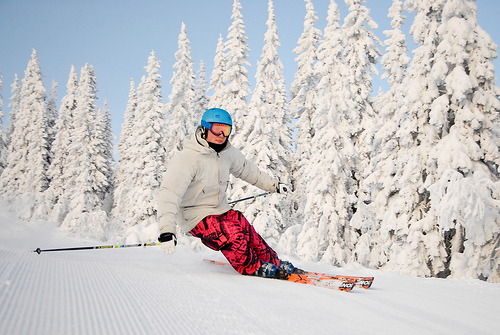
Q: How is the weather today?
A: It is clear.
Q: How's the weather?
A: It is clear.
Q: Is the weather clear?
A: Yes, it is clear.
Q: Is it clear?
A: Yes, it is clear.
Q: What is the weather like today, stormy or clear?
A: It is clear.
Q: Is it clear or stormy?
A: It is clear.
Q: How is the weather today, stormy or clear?
A: It is clear.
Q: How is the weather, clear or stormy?
A: It is clear.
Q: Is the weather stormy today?
A: No, it is clear.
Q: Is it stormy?
A: No, it is clear.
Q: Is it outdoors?
A: Yes, it is outdoors.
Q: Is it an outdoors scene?
A: Yes, it is outdoors.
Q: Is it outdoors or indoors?
A: It is outdoors.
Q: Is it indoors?
A: No, it is outdoors.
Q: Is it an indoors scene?
A: No, it is outdoors.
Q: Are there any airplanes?
A: No, there are no airplanes.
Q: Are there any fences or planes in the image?
A: No, there are no planes or fences.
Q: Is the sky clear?
A: Yes, the sky is clear.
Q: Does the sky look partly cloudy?
A: No, the sky is clear.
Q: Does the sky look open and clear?
A: Yes, the sky is open and clear.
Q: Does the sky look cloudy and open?
A: No, the sky is open but clear.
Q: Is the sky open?
A: Yes, the sky is open.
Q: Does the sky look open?
A: Yes, the sky is open.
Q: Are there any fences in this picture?
A: No, there are no fences.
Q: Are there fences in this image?
A: No, there are no fences.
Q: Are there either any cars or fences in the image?
A: No, there are no fences or cars.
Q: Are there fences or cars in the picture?
A: No, there are no fences or cars.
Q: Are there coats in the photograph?
A: Yes, there is a coat.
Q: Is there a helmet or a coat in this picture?
A: Yes, there is a coat.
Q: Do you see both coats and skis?
A: Yes, there are both a coat and skis.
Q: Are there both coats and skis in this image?
A: Yes, there are both a coat and skis.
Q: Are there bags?
A: No, there are no bags.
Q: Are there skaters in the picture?
A: No, there are no skaters.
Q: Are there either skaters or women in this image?
A: No, there are no skaters or women.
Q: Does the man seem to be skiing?
A: Yes, the man is skiing.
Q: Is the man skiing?
A: Yes, the man is skiing.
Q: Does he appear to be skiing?
A: Yes, the man is skiing.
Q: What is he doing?
A: The man is skiing.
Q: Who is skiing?
A: The man is skiing.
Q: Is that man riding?
A: No, the man is skiing.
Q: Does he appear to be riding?
A: No, the man is skiing.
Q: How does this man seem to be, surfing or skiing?
A: The man is skiing.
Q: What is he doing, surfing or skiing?
A: The man is skiing.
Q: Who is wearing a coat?
A: The man is wearing a coat.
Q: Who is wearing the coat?
A: The man is wearing a coat.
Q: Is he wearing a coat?
A: Yes, the man is wearing a coat.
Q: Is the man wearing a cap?
A: No, the man is wearing a coat.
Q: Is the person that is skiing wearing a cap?
A: No, the man is wearing a coat.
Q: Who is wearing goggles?
A: The man is wearing goggles.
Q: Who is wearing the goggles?
A: The man is wearing goggles.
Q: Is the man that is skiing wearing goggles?
A: Yes, the man is wearing goggles.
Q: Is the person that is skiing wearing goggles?
A: Yes, the man is wearing goggles.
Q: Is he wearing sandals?
A: No, the man is wearing goggles.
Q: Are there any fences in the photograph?
A: No, there are no fences.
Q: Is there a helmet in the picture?
A: Yes, there is a helmet.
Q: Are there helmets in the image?
A: Yes, there is a helmet.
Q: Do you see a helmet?
A: Yes, there is a helmet.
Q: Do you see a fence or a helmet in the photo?
A: Yes, there is a helmet.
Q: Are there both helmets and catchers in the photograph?
A: No, there is a helmet but no catchers.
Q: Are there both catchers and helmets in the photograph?
A: No, there is a helmet but no catchers.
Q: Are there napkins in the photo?
A: No, there are no napkins.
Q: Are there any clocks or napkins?
A: No, there are no napkins or clocks.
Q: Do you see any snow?
A: Yes, there is snow.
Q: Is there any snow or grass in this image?
A: Yes, there is snow.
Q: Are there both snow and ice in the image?
A: No, there is snow but no ice.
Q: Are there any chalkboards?
A: No, there are no chalkboards.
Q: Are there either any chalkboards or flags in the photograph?
A: No, there are no chalkboards or flags.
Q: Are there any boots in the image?
A: Yes, there are boots.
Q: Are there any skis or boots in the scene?
A: Yes, there are boots.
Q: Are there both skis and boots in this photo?
A: Yes, there are both boots and skis.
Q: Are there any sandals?
A: No, there are no sandals.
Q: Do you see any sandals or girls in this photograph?
A: No, there are no sandals or girls.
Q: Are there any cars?
A: No, there are no cars.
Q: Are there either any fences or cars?
A: No, there are no cars or fences.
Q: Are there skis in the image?
A: Yes, there are skis.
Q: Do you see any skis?
A: Yes, there are skis.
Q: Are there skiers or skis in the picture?
A: Yes, there are skis.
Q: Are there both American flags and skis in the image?
A: No, there are skis but no American flags.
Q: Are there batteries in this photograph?
A: No, there are no batteries.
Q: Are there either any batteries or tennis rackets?
A: No, there are no batteries or tennis rackets.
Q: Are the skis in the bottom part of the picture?
A: Yes, the skis are in the bottom of the image.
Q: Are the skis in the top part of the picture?
A: No, the skis are in the bottom of the image.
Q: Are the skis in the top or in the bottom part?
A: The skis are in the bottom of the image.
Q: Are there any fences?
A: No, there are no fences.